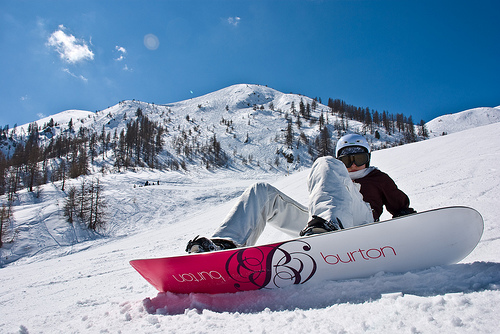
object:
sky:
[0, 0, 499, 131]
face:
[335, 146, 368, 174]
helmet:
[335, 133, 370, 158]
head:
[335, 133, 371, 178]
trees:
[0, 99, 227, 242]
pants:
[209, 155, 374, 248]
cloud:
[39, 22, 97, 66]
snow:
[37, 276, 91, 331]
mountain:
[0, 83, 399, 254]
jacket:
[352, 168, 418, 222]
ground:
[0, 167, 500, 333]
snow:
[17, 252, 118, 322]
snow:
[4, 258, 119, 332]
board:
[128, 205, 483, 294]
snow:
[20, 219, 199, 312]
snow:
[0, 83, 499, 334]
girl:
[186, 133, 417, 253]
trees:
[26, 123, 86, 188]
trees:
[112, 112, 172, 159]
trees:
[334, 100, 381, 126]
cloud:
[35, 24, 114, 82]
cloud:
[42, 21, 112, 84]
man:
[184, 133, 417, 254]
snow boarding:
[128, 205, 486, 294]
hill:
[0, 132, 499, 333]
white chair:
[323, 97, 426, 122]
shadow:
[141, 261, 500, 315]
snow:
[0, 121, 499, 334]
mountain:
[0, 83, 499, 159]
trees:
[319, 97, 428, 140]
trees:
[100, 101, 170, 167]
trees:
[7, 126, 91, 183]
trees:
[61, 179, 109, 230]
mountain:
[0, 83, 499, 242]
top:
[209, 84, 278, 107]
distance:
[0, 0, 498, 127]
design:
[224, 239, 319, 292]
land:
[45, 102, 303, 175]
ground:
[0, 285, 500, 334]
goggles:
[338, 152, 369, 168]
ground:
[20, 200, 129, 304]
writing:
[320, 246, 398, 265]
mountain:
[140, 83, 389, 159]